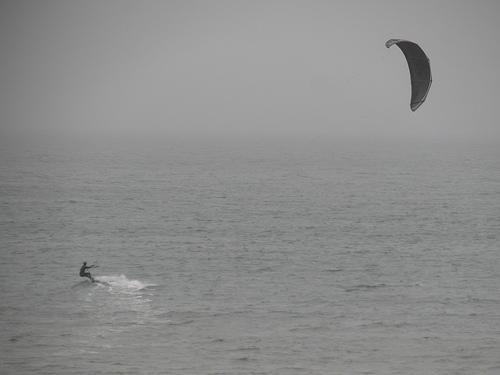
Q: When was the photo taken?
A: Daytime.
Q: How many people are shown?
A: One.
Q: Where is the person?
A: Water.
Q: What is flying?
A: Kite.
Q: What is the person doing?
A: Skiing.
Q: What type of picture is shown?
A: Black and white.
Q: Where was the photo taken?
A: In the sea.